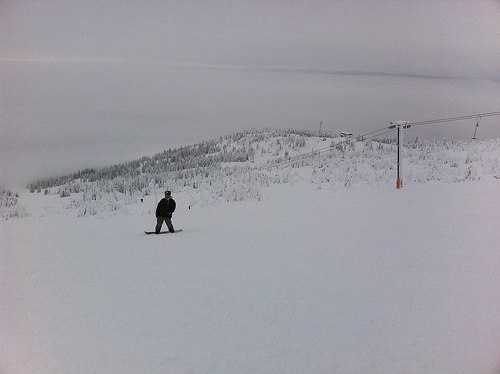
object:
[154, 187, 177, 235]
snowboarder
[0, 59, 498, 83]
line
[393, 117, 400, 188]
pole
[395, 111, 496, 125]
wires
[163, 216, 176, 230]
leg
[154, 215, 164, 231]
leg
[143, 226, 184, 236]
board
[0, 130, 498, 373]
snow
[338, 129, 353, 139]
structure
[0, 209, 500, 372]
path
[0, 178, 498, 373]
slope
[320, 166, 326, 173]
stubble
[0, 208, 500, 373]
ground